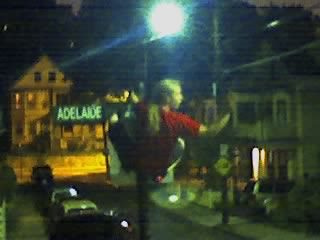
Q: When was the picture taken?
A: Nighttime.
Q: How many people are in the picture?
A: One.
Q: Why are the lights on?
A: It is dark.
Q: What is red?
A: Shirt.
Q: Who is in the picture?
A: Man.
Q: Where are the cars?
A: To the left.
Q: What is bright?
A: The light.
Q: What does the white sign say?
A: ADELAJOE.